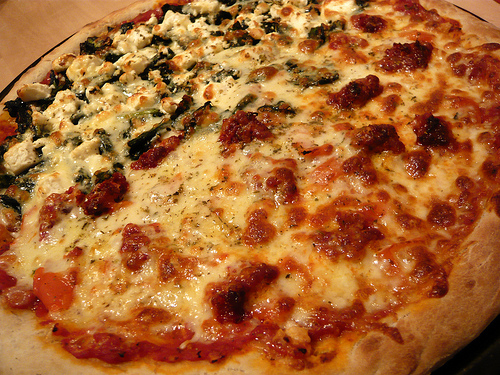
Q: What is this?
A: Pizza.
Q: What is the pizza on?
A: A pan.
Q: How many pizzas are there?
A: One.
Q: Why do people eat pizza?
A: They're hungry.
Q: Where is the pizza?
A: On a pan.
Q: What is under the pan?
A: A table.